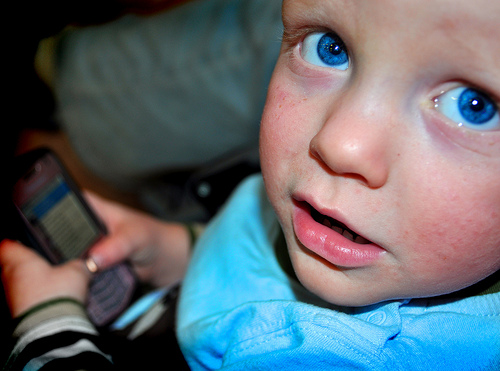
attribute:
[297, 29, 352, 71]
eye — blue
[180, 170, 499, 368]
shirt — blue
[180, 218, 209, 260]
sleeve — striped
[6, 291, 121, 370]
sleeve — striped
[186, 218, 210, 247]
stripes — white, black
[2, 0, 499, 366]
boy — little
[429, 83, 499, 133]
eye — blue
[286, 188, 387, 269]
mouth — open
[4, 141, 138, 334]
phone — small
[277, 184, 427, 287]
lips — light pink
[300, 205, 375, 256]
teeth — barely visible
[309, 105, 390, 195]
nose — small